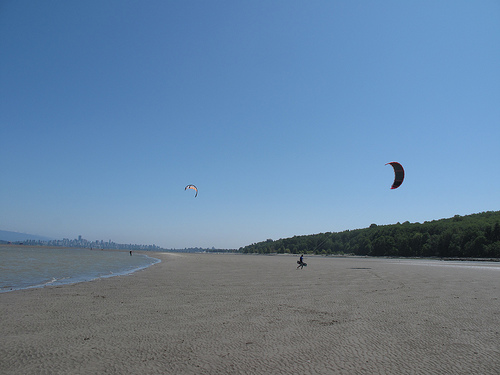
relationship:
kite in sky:
[383, 151, 415, 198] [243, 62, 298, 113]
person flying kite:
[293, 249, 323, 276] [383, 151, 415, 198]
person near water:
[293, 249, 323, 276] [41, 247, 81, 283]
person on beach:
[293, 249, 323, 276] [164, 273, 248, 347]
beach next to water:
[164, 273, 248, 347] [41, 247, 81, 283]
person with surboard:
[293, 249, 323, 276] [300, 262, 307, 269]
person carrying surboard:
[293, 249, 323, 276] [300, 262, 307, 269]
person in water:
[293, 249, 323, 276] [41, 247, 81, 283]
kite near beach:
[383, 151, 415, 198] [164, 273, 248, 347]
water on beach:
[41, 247, 81, 283] [164, 273, 248, 347]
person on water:
[293, 249, 323, 276] [41, 247, 81, 283]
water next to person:
[41, 247, 81, 283] [293, 249, 323, 276]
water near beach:
[41, 247, 81, 283] [164, 273, 248, 347]